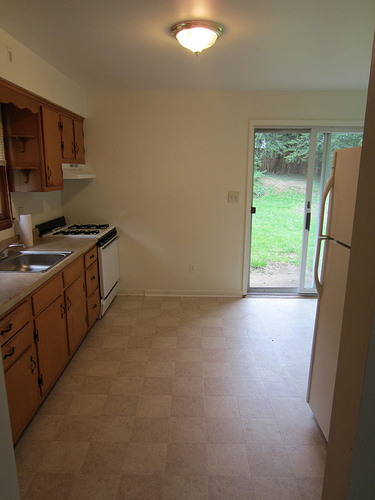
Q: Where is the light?
A: On the ceiling.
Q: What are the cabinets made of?
A: Wood.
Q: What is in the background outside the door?
A: Pine trees.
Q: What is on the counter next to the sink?
A: Paper towels.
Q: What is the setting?
A: A kitchen.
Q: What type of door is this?
A: A sliding door.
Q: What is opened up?
A: The screen door.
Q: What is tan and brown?
A: The floor.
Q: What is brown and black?
A: The cabinets.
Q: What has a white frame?
A: The door.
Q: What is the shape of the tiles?
A: Square.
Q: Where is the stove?
A: In the corner.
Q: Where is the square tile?
A: On the floor.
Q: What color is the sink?
A: Silver.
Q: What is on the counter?
A: Paper towels.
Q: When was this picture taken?
A: Daytime.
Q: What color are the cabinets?
A: Brown.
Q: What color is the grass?
A: Green.